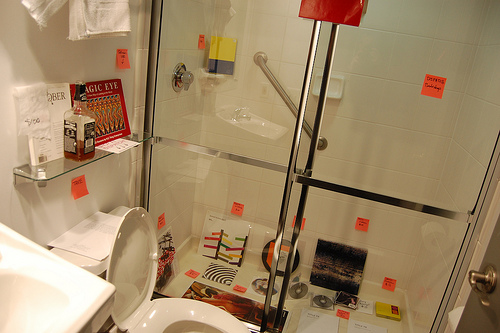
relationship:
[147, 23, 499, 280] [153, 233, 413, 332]
shower has floor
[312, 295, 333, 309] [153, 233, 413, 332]
cd on floor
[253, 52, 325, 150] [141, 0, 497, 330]
handle in shower.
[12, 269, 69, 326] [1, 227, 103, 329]
part of sink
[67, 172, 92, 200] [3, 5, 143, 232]
post-it on wall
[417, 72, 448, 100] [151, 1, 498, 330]
post-it on wall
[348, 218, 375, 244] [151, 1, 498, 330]
post on wall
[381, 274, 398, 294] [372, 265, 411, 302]
post it on wall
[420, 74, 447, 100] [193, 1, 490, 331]
post-it on wall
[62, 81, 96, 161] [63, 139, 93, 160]
bottle of liquor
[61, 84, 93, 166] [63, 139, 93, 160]
glass of liquor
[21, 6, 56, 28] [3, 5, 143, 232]
hand towel hanging on wall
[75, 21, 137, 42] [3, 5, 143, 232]
hand towel hanging on wall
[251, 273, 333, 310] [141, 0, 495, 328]
cd's inside shower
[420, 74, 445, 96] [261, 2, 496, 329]
post-it on shower door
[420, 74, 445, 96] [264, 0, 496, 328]
post-it on glass door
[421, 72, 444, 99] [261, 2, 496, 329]
red post-it on shower door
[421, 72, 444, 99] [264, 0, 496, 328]
red post-it on glass door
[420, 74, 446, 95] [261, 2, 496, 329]
neon post-it on shower door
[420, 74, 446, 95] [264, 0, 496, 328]
neon post-it on glass door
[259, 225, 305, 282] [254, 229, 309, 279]
record in a cover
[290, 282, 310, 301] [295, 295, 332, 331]
cd in paper